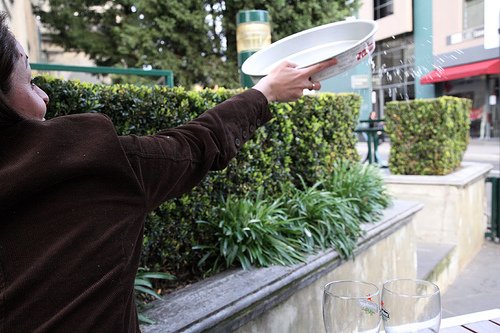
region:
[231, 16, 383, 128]
Woman holding white dish.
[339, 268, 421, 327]
2 glasses near person.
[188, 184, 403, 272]
Green plants near bushes.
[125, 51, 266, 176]
Green bushes near plants.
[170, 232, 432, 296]
Concrete wall near woman.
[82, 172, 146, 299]
Woman is wearing brown jacket.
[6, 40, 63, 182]
Woman has brown hair.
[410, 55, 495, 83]
Red canopy on building across street.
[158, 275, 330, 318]
Woman is sitting at a table.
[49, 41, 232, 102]
Green railing near woman.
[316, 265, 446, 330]
Two empty glasses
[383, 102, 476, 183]
Shrubs on a city walk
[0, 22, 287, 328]
Person in a brown shirt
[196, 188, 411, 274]
Decorative grass near sidewalk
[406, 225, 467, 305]
Concrete steps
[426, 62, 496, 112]
Front of a store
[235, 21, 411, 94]
Hand holding empty pan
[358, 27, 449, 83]
Liquid coming out of pan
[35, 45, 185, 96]
Handrail near sidewalk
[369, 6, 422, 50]
Window on a store front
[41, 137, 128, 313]
Woman is wearing brown jacket.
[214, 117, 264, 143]
4 buttons on woman's sleeve.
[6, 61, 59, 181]
Woman has dark hair.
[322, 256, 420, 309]
2 glasses on table.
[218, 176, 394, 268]
Green plants above concrete wall.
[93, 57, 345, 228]
Green manicured bushes.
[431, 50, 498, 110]
Red canopy on building across street.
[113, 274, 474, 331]
Woman is sitting at a table.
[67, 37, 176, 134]
Green railing near woman.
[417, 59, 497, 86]
red awning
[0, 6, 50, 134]
a woman with brown hair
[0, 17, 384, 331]
woman with brown hair holding a white dish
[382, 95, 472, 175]
green shrubs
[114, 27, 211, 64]
a green tree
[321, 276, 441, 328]
2 drinking glasses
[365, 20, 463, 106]
droplets of water in the air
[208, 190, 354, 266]
green plants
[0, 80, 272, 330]
a brown jacket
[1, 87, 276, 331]
brown buttons on a brown jacket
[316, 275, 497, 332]
Two glasses on a table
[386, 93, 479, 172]
A square-shaped bush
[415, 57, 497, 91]
A red awning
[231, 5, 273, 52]
A cylinder-shaped light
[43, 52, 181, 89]
A green metal railing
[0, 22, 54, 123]
The head of a woman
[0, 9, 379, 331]
A woman holding a metal pan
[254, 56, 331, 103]
A woman's hand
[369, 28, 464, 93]
Drops of water in the air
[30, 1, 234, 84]
A green tree